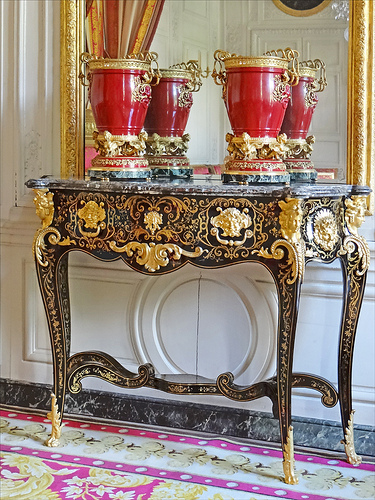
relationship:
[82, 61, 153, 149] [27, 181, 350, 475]
vase on table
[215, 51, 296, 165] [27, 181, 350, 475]
vase on table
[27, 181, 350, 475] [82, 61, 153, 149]
table under vase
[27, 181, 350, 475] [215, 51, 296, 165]
table under vase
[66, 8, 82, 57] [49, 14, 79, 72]
mirror has frame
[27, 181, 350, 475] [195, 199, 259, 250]
table has details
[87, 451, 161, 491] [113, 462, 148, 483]
rug has designs